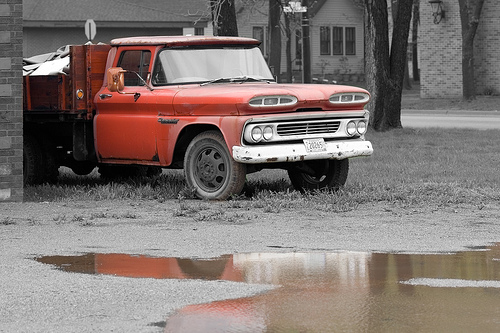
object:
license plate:
[302, 136, 329, 153]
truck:
[22, 35, 372, 201]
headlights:
[248, 126, 263, 141]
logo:
[156, 117, 181, 125]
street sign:
[81, 19, 97, 41]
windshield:
[150, 47, 276, 88]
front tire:
[181, 126, 244, 201]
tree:
[363, 2, 413, 133]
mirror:
[103, 65, 155, 101]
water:
[26, 243, 499, 333]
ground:
[0, 96, 498, 332]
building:
[413, 2, 499, 101]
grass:
[0, 124, 498, 229]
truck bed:
[20, 42, 110, 187]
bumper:
[227, 137, 374, 165]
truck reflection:
[171, 252, 233, 283]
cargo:
[20, 41, 72, 77]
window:
[330, 25, 347, 58]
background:
[0, 0, 499, 332]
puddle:
[25, 238, 500, 332]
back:
[82, 21, 98, 42]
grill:
[276, 120, 343, 136]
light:
[261, 126, 275, 142]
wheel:
[283, 155, 349, 196]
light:
[345, 118, 358, 135]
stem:
[361, 0, 411, 133]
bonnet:
[110, 33, 262, 46]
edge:
[455, 13, 468, 99]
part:
[440, 49, 454, 63]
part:
[110, 72, 117, 81]